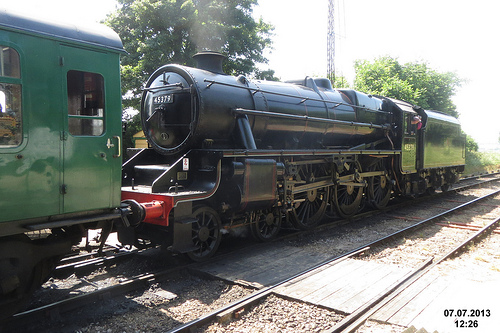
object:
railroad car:
[0, 8, 125, 297]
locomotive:
[120, 51, 468, 263]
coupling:
[119, 189, 176, 229]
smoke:
[190, 0, 227, 55]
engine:
[137, 48, 397, 158]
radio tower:
[327, 0, 339, 90]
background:
[1, 0, 496, 166]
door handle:
[113, 135, 121, 159]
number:
[151, 91, 175, 107]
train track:
[2, 169, 500, 332]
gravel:
[2, 170, 499, 332]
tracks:
[0, 171, 497, 331]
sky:
[2, 0, 500, 114]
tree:
[100, 0, 278, 147]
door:
[57, 39, 122, 216]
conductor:
[411, 112, 423, 136]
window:
[400, 110, 417, 135]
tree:
[331, 54, 470, 122]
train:
[1, 0, 465, 313]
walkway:
[86, 224, 499, 332]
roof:
[0, 0, 128, 53]